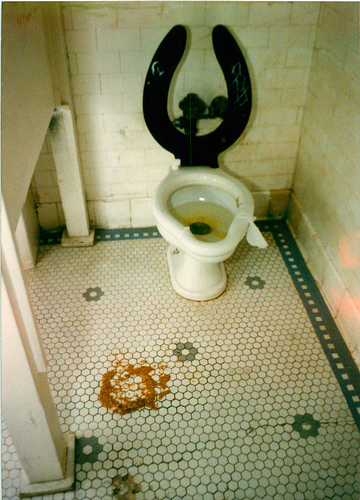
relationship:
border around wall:
[36, 218, 358, 430] [28, 0, 359, 365]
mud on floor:
[96, 358, 173, 416] [0, 219, 359, 498]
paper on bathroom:
[252, 213, 292, 256] [1, 1, 358, 499]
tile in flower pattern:
[174, 341, 198, 361] [242, 279, 291, 355]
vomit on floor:
[97, 351, 172, 414] [20, 227, 360, 499]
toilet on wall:
[145, 24, 253, 302] [55, 3, 326, 252]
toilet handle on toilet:
[170, 115, 182, 129] [137, 25, 263, 303]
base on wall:
[277, 205, 359, 362] [280, 1, 358, 360]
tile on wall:
[285, 254, 342, 318] [261, 3, 358, 424]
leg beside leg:
[48, 126, 87, 223] [1, 258, 52, 374]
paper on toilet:
[245, 213, 269, 249] [137, 25, 263, 303]